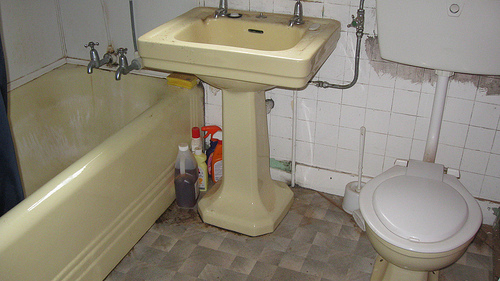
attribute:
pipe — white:
[422, 69, 457, 161]